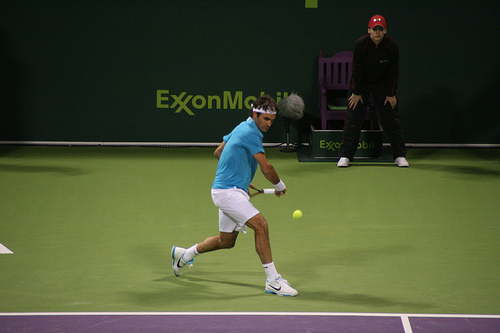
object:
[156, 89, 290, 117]
logo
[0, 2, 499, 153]
background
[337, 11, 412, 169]
man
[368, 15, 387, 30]
cap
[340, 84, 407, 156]
pants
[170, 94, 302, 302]
man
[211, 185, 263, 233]
shorts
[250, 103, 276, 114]
headband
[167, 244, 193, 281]
shoes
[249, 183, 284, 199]
racket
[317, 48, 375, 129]
chair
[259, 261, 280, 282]
socks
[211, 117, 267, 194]
shirt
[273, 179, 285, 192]
wristband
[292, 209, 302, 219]
ball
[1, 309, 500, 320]
line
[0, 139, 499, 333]
court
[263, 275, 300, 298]
foot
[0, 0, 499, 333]
air